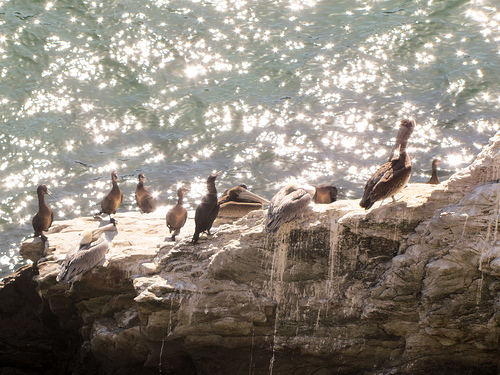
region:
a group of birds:
[13, 108, 432, 300]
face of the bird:
[373, 105, 421, 145]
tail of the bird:
[186, 224, 208, 246]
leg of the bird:
[129, 199, 139, 216]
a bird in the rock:
[327, 80, 430, 242]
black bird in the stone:
[196, 166, 237, 262]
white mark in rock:
[266, 242, 305, 325]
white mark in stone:
[304, 224, 348, 290]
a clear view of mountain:
[90, 230, 496, 354]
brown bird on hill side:
[22, 180, 59, 236]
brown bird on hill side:
[101, 167, 122, 199]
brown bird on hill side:
[130, 170, 146, 200]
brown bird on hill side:
[162, 185, 189, 232]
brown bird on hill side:
[200, 168, 221, 235]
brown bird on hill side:
[225, 177, 261, 213]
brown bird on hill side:
[305, 184, 335, 204]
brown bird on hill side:
[365, 110, 408, 206]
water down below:
[0, 0, 498, 170]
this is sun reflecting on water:
[236, 107, 283, 135]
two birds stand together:
[167, 174, 222, 244]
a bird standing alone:
[359, 115, 418, 210]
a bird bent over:
[266, 181, 343, 231]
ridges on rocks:
[361, 244, 427, 331]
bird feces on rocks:
[271, 228, 288, 280]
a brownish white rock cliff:
[1, 203, 497, 370]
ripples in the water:
[14, 45, 37, 72]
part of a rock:
[462, 310, 476, 331]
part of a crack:
[361, 290, 367, 313]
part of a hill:
[236, 253, 239, 266]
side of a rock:
[215, 274, 222, 286]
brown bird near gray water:
[18, 173, 62, 238]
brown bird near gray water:
[87, 158, 129, 203]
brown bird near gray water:
[128, 166, 158, 208]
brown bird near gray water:
[164, 182, 195, 233]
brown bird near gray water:
[200, 169, 218, 230]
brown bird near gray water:
[308, 172, 343, 204]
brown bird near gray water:
[357, 112, 418, 232]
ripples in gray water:
[31, 45, 96, 95]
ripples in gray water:
[210, 23, 251, 85]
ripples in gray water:
[327, 55, 361, 99]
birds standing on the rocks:
[25, 124, 450, 264]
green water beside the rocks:
[3, 8, 465, 260]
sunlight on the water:
[21, 12, 480, 172]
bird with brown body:
[348, 112, 421, 209]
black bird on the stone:
[186, 172, 224, 237]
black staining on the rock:
[257, 219, 407, 279]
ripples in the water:
[8, 10, 476, 193]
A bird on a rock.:
[190, 175, 220, 250]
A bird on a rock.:
[159, 183, 182, 240]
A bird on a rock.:
[132, 164, 159, 213]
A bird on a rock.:
[97, 164, 128, 221]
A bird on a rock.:
[261, 175, 328, 225]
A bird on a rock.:
[338, 123, 417, 213]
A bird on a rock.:
[421, 152, 439, 188]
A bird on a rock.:
[358, 115, 446, 216]